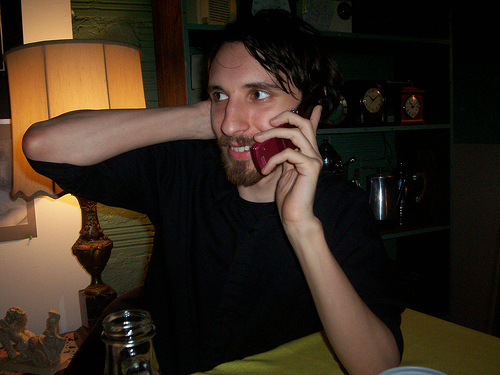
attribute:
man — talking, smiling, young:
[19, 6, 404, 375]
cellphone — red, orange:
[249, 79, 329, 171]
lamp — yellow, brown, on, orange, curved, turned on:
[7, 38, 146, 334]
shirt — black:
[28, 134, 407, 371]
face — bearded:
[209, 41, 297, 190]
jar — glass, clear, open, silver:
[377, 171, 423, 227]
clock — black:
[345, 72, 394, 127]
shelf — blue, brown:
[153, 1, 459, 323]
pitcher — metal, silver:
[394, 160, 430, 231]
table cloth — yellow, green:
[190, 298, 498, 375]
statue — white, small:
[5, 305, 72, 374]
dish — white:
[372, 364, 449, 375]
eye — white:
[251, 89, 273, 100]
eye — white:
[212, 92, 231, 103]